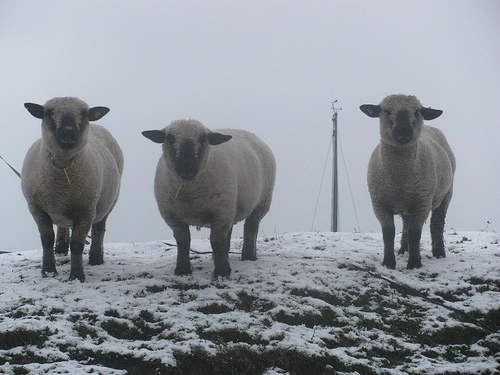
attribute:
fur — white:
[366, 121, 456, 216]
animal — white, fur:
[354, 88, 460, 277]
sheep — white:
[355, 90, 459, 269]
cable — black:
[160, 239, 499, 336]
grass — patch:
[102, 320, 150, 338]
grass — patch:
[200, 355, 246, 373]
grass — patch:
[276, 352, 319, 372]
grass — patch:
[386, 320, 416, 333]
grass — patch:
[436, 325, 475, 346]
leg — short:
[170, 223, 193, 276]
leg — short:
[206, 224, 233, 276]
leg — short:
[240, 213, 262, 260]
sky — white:
[215, 46, 310, 125]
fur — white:
[18, 123, 123, 225]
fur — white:
[142, 118, 276, 277]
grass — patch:
[1, 230, 498, 373]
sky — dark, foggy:
[220, 43, 363, 98]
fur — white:
[172, 146, 264, 246]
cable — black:
[346, 260, 499, 338]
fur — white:
[19, 96, 125, 261]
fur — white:
[358, 93, 456, 268]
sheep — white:
[19, 96, 124, 283]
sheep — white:
[142, 118, 273, 279]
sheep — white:
[360, 94, 455, 269]